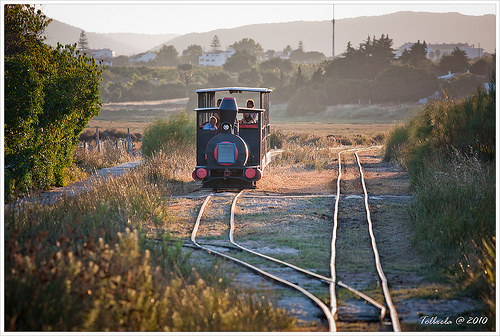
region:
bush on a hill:
[12, 233, 311, 333]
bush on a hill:
[448, 229, 493, 316]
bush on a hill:
[408, 146, 489, 239]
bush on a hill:
[384, 121, 412, 163]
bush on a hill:
[411, 93, 458, 142]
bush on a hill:
[446, 87, 492, 159]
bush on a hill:
[11, 105, 88, 187]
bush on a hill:
[46, 50, 104, 130]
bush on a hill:
[9, 58, 44, 134]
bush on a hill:
[283, 83, 332, 120]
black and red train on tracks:
[195, 73, 286, 207]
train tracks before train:
[194, 200, 261, 266]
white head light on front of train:
[218, 121, 233, 141]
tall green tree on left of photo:
[31, 103, 65, 168]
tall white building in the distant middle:
[193, 38, 232, 73]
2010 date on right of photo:
[455, 303, 498, 323]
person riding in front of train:
[195, 111, 221, 134]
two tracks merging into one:
[230, 240, 412, 335]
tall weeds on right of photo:
[423, 154, 463, 214]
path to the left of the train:
[101, 164, 136, 186]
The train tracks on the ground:
[179, 199, 406, 329]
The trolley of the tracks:
[183, 69, 277, 186]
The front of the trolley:
[193, 130, 261, 184]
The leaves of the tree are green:
[10, 25, 93, 182]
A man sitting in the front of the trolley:
[198, 113, 221, 133]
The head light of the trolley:
[216, 118, 236, 136]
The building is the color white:
[194, 39, 238, 74]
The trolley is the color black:
[181, 74, 269, 179]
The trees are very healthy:
[101, 40, 446, 111]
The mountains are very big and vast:
[13, 8, 496, 64]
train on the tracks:
[186, 80, 281, 191]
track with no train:
[325, 153, 389, 323]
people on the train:
[207, 95, 254, 132]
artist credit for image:
[397, 293, 494, 325]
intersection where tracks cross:
[293, 244, 374, 316]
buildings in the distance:
[198, 43, 232, 68]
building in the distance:
[397, 33, 481, 61]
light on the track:
[216, 119, 239, 137]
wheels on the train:
[191, 183, 259, 193]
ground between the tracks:
[247, 205, 314, 240]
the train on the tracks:
[182, 68, 283, 182]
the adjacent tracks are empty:
[327, 140, 407, 313]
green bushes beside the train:
[10, 43, 108, 191]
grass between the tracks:
[261, 163, 335, 258]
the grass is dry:
[241, 161, 344, 268]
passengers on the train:
[200, 112, 219, 125]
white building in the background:
[191, 41, 229, 66]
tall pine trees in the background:
[309, 36, 429, 111]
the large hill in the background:
[191, 10, 493, 50]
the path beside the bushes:
[14, 150, 151, 216]